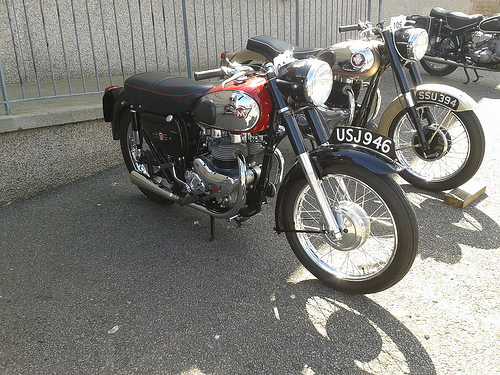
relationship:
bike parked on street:
[100, 46, 419, 295] [1, 60, 500, 374]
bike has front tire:
[100, 46, 419, 295] [279, 161, 420, 294]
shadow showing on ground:
[0, 59, 499, 373] [1, 60, 499, 374]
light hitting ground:
[179, 84, 500, 374] [1, 60, 499, 374]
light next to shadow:
[179, 84, 500, 374] [0, 59, 499, 373]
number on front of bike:
[360, 131, 392, 154] [100, 46, 419, 295]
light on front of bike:
[276, 57, 335, 108] [100, 46, 419, 295]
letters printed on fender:
[336, 128, 363, 143] [274, 125, 407, 234]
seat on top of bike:
[122, 71, 215, 113] [100, 46, 419, 295]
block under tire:
[443, 179, 487, 210] [388, 102, 486, 192]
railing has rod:
[0, 0, 372, 117] [22, 0, 42, 97]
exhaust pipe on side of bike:
[129, 169, 178, 204] [100, 46, 419, 295]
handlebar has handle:
[192, 45, 296, 87] [193, 67, 224, 81]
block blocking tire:
[443, 179, 487, 210] [388, 102, 486, 192]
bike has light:
[100, 46, 419, 295] [276, 57, 335, 108]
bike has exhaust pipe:
[100, 46, 419, 295] [129, 169, 178, 204]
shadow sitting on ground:
[0, 59, 499, 373] [1, 60, 499, 374]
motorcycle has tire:
[218, 13, 486, 192] [388, 102, 486, 192]